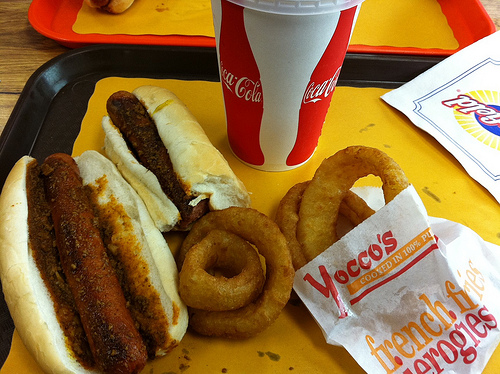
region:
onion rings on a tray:
[151, 138, 445, 336]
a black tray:
[16, 63, 494, 338]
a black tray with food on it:
[16, 58, 493, 317]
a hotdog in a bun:
[74, 83, 269, 241]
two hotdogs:
[0, 86, 290, 363]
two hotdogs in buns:
[7, 87, 313, 350]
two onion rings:
[163, 185, 289, 372]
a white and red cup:
[185, 1, 345, 201]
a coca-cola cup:
[188, 4, 380, 188]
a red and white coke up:
[204, 2, 371, 189]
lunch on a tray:
[2, 3, 499, 368]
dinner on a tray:
[2, 8, 498, 369]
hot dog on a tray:
[102, 83, 237, 213]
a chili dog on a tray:
[2, 145, 178, 372]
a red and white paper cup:
[211, 3, 363, 170]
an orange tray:
[23, 0, 497, 57]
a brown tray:
[0, 41, 480, 371]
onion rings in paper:
[278, 147, 495, 372]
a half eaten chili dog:
[101, 82, 240, 229]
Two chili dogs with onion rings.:
[0, 85, 498, 371]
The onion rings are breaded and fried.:
[171, 146, 419, 336]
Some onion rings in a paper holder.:
[291, 182, 499, 372]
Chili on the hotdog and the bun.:
[33, 153, 163, 357]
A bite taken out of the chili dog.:
[148, 173, 251, 235]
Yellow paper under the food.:
[4, 70, 497, 372]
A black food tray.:
[0, 45, 495, 371]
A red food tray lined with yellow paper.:
[23, 8, 498, 53]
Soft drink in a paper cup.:
[207, 0, 359, 170]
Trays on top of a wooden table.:
[1, 3, 498, 369]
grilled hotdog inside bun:
[0, 139, 187, 370]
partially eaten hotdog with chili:
[96, 72, 270, 247]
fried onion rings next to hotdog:
[2, 65, 324, 367]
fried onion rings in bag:
[272, 155, 498, 366]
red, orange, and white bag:
[308, 249, 490, 371]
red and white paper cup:
[199, 7, 363, 195]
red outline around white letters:
[404, 53, 498, 159]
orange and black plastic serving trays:
[7, 2, 227, 219]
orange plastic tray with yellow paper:
[10, 0, 212, 52]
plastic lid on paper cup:
[207, 0, 372, 45]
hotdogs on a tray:
[5, 46, 345, 371]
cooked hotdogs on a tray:
[17, 69, 300, 372]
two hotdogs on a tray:
[25, 19, 320, 356]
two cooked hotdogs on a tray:
[43, 59, 305, 361]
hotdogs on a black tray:
[41, 29, 207, 371]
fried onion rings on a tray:
[137, 166, 499, 363]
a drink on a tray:
[165, 5, 499, 280]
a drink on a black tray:
[169, 21, 416, 198]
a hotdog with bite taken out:
[71, 43, 297, 263]